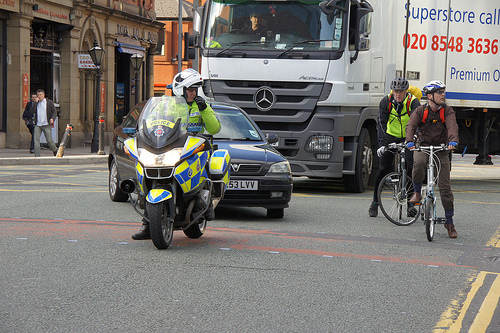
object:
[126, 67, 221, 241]
person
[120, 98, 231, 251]
motorcycle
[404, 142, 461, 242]
bike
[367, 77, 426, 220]
person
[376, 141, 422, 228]
bike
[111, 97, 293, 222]
car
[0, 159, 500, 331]
street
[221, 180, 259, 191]
license plate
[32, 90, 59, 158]
person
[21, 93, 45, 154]
person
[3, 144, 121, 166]
sidewalk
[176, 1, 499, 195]
truck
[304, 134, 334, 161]
headlight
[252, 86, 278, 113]
emblem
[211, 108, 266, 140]
windshield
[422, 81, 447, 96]
helmet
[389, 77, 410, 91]
helmet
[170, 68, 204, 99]
helmet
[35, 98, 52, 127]
shirt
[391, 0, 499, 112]
box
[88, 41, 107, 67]
light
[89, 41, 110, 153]
pole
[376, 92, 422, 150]
jacket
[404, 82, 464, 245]
men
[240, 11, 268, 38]
man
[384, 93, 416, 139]
vest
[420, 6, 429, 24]
writing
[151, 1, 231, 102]
building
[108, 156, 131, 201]
tire